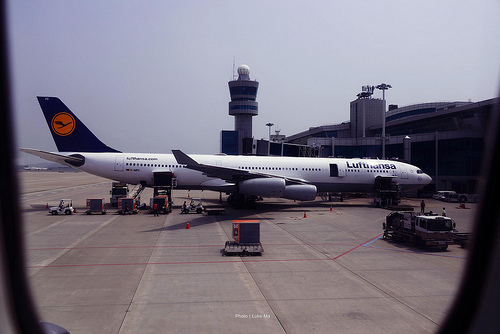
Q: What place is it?
A: It is an airport.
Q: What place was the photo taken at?
A: It was taken at the airport.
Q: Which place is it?
A: It is an airport.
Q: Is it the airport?
A: Yes, it is the airport.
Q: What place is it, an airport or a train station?
A: It is an airport.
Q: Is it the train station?
A: No, it is the airport.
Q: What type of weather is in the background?
A: It is clear.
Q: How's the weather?
A: It is clear.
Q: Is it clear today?
A: Yes, it is clear.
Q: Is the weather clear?
A: Yes, it is clear.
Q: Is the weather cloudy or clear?
A: It is clear.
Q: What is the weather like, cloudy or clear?
A: It is clear.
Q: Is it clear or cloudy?
A: It is clear.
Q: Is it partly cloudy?
A: No, it is clear.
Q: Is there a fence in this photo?
A: No, there are no fences.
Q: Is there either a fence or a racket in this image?
A: No, there are no fences or rackets.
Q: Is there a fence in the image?
A: No, there are no fences.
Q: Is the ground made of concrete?
A: Yes, the ground is made of concrete.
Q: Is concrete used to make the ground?
A: Yes, the ground is made of concrete.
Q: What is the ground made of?
A: The ground is made of concrete.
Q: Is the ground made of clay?
A: No, the ground is made of cement.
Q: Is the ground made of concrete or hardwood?
A: The ground is made of concrete.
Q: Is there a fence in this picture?
A: No, there are no fences.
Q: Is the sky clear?
A: Yes, the sky is clear.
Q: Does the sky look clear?
A: Yes, the sky is clear.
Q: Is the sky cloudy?
A: No, the sky is clear.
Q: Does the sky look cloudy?
A: No, the sky is clear.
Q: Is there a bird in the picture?
A: No, there are no birds.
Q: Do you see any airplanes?
A: Yes, there is an airplane.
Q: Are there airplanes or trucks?
A: Yes, there is an airplane.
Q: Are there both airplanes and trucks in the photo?
A: Yes, there are both an airplane and a truck.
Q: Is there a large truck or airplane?
A: Yes, there is a large airplane.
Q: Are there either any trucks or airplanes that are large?
A: Yes, the airplane is large.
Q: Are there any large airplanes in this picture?
A: Yes, there is a large airplane.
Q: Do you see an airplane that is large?
A: Yes, there is an airplane that is large.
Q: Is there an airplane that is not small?
A: Yes, there is a large airplane.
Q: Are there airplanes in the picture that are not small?
A: Yes, there is a large airplane.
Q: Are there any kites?
A: No, there are no kites.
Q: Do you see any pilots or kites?
A: No, there are no kites or pilots.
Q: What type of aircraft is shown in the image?
A: The aircraft is an airplane.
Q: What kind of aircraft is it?
A: The aircraft is an airplane.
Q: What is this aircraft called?
A: This is an airplane.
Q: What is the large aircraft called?
A: The aircraft is an airplane.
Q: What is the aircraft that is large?
A: The aircraft is an airplane.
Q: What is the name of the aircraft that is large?
A: The aircraft is an airplane.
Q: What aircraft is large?
A: The aircraft is an airplane.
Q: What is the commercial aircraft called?
A: The aircraft is an airplane.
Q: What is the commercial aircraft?
A: The aircraft is an airplane.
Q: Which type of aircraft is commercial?
A: The aircraft is an airplane.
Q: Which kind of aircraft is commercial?
A: The aircraft is an airplane.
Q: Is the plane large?
A: Yes, the plane is large.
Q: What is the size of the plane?
A: The plane is large.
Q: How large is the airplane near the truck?
A: The plane is large.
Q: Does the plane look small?
A: No, the plane is large.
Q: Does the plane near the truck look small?
A: No, the airplane is large.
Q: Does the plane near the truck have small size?
A: No, the airplane is large.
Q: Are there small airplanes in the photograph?
A: No, there is an airplane but it is large.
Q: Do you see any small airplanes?
A: No, there is an airplane but it is large.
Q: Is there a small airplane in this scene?
A: No, there is an airplane but it is large.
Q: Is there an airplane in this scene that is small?
A: No, there is an airplane but it is large.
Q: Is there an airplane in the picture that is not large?
A: No, there is an airplane but it is large.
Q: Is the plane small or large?
A: The plane is large.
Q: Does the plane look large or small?
A: The plane is large.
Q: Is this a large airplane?
A: Yes, this is a large airplane.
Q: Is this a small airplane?
A: No, this is a large airplane.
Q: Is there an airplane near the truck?
A: Yes, there is an airplane near the truck.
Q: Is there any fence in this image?
A: No, there are no fences.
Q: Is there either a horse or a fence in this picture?
A: No, there are no fences or horses.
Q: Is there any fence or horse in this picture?
A: No, there are no fences or horses.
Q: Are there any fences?
A: No, there are no fences.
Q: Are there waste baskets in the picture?
A: No, there are no waste baskets.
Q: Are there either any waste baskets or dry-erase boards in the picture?
A: No, there are no waste baskets or dry-erase boards.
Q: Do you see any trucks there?
A: Yes, there is a truck.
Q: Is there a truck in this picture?
A: Yes, there is a truck.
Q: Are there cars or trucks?
A: Yes, there is a truck.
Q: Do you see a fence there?
A: No, there are no fences.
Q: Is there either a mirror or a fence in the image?
A: No, there are no fences or mirrors.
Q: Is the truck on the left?
A: Yes, the truck is on the left of the image.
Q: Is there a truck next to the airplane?
A: Yes, there is a truck next to the airplane.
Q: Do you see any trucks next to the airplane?
A: Yes, there is a truck next to the airplane.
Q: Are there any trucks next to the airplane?
A: Yes, there is a truck next to the airplane.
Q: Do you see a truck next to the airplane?
A: Yes, there is a truck next to the airplane.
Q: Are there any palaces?
A: No, there are no palaces.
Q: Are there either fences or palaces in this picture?
A: No, there are no palaces or fences.